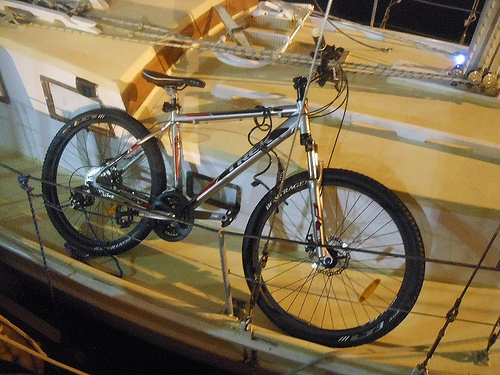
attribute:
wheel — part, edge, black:
[240, 165, 425, 349]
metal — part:
[85, 168, 114, 195]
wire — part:
[249, 102, 285, 196]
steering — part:
[295, 28, 349, 86]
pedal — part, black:
[218, 203, 242, 231]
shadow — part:
[2, 148, 268, 320]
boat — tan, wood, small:
[1, 2, 499, 374]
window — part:
[184, 172, 241, 209]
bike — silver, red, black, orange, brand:
[38, 26, 427, 350]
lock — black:
[250, 103, 285, 201]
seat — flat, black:
[140, 67, 207, 90]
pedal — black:
[115, 200, 136, 230]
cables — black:
[299, 63, 351, 244]